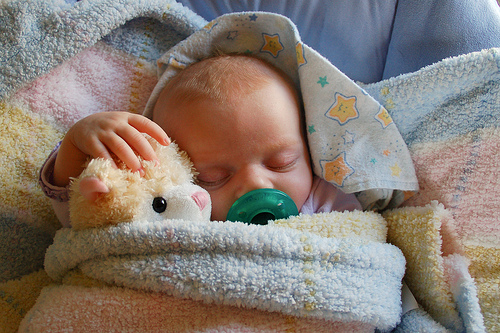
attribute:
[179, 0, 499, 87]
pillow — blue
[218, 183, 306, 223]
pacifier — green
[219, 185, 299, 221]
mouth — infant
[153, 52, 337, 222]
infant — sleeping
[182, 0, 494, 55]
pillow — big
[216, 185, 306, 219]
pacifier — green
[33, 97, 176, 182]
hand — baby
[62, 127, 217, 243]
teddy — small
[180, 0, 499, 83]
pad — Blue cushioned crib bumper 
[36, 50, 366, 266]
baby — newborn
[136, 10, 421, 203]
cloth — blue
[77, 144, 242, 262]
teddy — brown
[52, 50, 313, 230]
baby — newborn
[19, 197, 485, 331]
blanket — fluffy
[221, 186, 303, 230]
pacifier — green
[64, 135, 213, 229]
stuffed bear — yellow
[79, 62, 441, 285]
blanket — blue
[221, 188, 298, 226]
sucker — green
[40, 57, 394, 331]
baby — sleeping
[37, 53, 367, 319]
baby — sleeping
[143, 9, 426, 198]
blanket — fluffy, striped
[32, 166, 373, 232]
gament — infant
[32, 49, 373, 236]
baby — sleeping